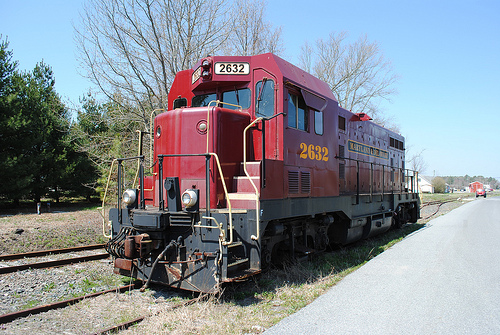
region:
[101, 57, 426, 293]
the train is outdoors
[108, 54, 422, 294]
the train is red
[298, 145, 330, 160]
the train has numbers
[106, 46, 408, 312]
the train is on the track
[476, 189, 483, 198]
a car on the road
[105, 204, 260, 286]
the front is black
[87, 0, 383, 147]
the trees have not leaves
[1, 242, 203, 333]
the tracks are brown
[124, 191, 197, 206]
the train has headlights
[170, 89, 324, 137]
the train has windows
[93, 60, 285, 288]
front of red train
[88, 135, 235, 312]
stairs on front of train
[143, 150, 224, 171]
metal railings on stairs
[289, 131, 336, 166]
yellow numbers on side of train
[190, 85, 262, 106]
front window on train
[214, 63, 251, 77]
black numbers on top of train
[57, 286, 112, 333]
steel railroad tracks on ground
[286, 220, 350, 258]
wheels on bottom of train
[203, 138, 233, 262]
handle of a train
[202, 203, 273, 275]
steps of a train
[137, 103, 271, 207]
front of a train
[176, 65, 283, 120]
window of a train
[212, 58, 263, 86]
number of a train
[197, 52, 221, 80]
light of a train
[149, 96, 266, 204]
engine of a train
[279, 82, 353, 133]
window of a train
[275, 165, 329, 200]
vents of a train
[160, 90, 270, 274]
The front of a locomotive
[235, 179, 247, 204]
Stairs of a locomotive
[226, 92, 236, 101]
Window reflecting light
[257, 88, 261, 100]
A wiper on the window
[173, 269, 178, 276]
Rust on the locomotive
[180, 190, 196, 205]
The front headlight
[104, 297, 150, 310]
Grass between the tracks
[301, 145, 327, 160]
Numbers on the train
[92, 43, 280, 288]
front of red train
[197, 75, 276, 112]
front windows of train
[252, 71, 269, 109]
window wiper on front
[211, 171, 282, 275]
stairs on front of train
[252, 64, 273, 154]
front door to train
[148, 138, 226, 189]
safety railings on front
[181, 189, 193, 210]
light on front of train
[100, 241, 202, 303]
front bumper on train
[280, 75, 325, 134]
side windows on train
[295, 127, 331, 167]
yellow numbers on train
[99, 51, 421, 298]
a red train on a track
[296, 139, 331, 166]
yellow letters on the side of a train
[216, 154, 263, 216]
steps on the front of a train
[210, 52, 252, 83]
number of train at top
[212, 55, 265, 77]
number of train at top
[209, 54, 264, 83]
number of train at top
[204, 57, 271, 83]
number of train at top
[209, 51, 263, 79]
number of train at top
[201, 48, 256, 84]
number of train at top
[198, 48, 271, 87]
number of train at top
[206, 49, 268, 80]
number of train at top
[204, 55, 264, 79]
number of train at top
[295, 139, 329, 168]
yellow numbers on the train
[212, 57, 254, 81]
black numbers on the train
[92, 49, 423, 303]
a red train engine